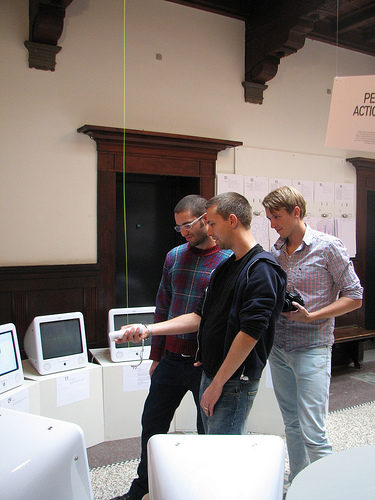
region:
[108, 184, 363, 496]
three men looking at computers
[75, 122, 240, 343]
wood door frame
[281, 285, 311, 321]
camera held by man wearing light blue jeans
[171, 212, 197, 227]
glasses worn by a man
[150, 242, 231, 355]
shirt worn by man wearing glasses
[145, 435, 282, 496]
back of a computer monitor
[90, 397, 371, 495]
white rug on the floor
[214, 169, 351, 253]
area behind men with papers on the wall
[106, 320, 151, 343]
something white being held by middle man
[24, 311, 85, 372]
front of a monitor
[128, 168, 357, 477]
Three men in a room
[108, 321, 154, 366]
Wii remote in the man's hand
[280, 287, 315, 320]
Black camera in the man's hand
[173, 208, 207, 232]
Glasses on the man's face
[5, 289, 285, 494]
White tv's in a semi-circle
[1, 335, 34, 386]
One monitor is on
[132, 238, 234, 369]
Plaid sweater on the man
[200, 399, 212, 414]
Wedding ring on the man's finger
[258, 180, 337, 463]
Man wearing a button up shirt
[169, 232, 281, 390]
The hoodie is unzipped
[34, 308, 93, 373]
white computer monitor on table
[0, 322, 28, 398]
white computer monitor that is powered on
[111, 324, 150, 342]
wii remote controller in hand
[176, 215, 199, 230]
white glasses on man's face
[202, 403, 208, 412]
ring on man's finger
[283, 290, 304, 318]
camera held in man's left hand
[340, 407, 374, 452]
white rug on the ground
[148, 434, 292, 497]
back part of monitor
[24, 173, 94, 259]
beige painted wall of room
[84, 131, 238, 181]
wooden door way in room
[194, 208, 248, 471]
BOY PLAYING NINTENDO WII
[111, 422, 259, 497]
WHITE COMPUTER MONITOR ON BOX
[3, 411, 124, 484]
WHITE COMPUTER MONITOR ON BOX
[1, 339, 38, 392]
WHITE COMPUTER MONITOR ON BOX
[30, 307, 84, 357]
WHITE COMPUTER MONITOR ON BOX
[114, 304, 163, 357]
WHITE COMPUTER MONITOR ON BOX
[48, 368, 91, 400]
WHITE PAPER ON WHITE BOX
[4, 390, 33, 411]
WHITE PAPER ON WHITE BOX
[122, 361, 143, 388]
WHITE PAPER ON WHITE BOX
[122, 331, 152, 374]
SMALL LOOP HANGING FROM REMOTE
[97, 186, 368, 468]
three guys standing trying out video games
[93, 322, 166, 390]
man holding video game controller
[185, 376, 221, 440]
man wearing wedding ring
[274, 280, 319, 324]
man holding black camera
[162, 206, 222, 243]
man wearing white rimmed glasses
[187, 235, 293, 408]
navy blue sweater hoodie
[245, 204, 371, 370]
man wearing plaid shirt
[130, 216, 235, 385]
man wearing plaid sweater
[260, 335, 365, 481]
man wearing blue jeans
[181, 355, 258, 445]
man wearing blue jeans